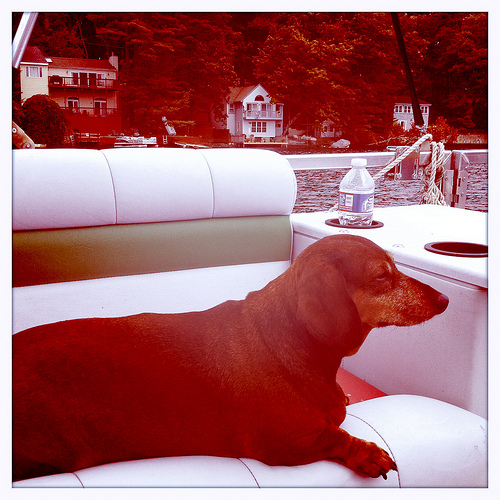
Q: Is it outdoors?
A: Yes, it is outdoors.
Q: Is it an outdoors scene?
A: Yes, it is outdoors.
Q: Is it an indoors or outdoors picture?
A: It is outdoors.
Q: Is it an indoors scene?
A: No, it is outdoors.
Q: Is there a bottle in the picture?
A: Yes, there is a bottle.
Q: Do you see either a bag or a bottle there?
A: Yes, there is a bottle.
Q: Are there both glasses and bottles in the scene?
A: No, there is a bottle but no glasses.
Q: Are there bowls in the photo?
A: No, there are no bowls.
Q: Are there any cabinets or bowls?
A: No, there are no bowls or cabinets.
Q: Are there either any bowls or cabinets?
A: No, there are no bowls or cabinets.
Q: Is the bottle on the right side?
A: Yes, the bottle is on the right of the image.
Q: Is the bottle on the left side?
A: No, the bottle is on the right of the image.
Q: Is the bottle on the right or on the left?
A: The bottle is on the right of the image.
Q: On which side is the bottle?
A: The bottle is on the right of the image.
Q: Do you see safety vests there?
A: No, there are no safety vests.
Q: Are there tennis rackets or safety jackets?
A: No, there are no safety jackets or tennis rackets.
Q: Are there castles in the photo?
A: No, there are no castles.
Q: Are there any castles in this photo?
A: No, there are no castles.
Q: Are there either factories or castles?
A: No, there are no castles or factories.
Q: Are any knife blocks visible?
A: No, there are no knife blocks.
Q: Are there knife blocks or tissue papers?
A: No, there are no knife blocks or tissue papers.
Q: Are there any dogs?
A: Yes, there is a dog.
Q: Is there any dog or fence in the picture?
A: Yes, there is a dog.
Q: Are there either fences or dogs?
A: Yes, there is a dog.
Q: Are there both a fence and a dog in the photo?
A: No, there is a dog but no fences.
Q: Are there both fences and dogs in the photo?
A: No, there is a dog but no fences.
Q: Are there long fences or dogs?
A: Yes, there is a long dog.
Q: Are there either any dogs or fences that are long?
A: Yes, the dog is long.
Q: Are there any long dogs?
A: Yes, there is a long dog.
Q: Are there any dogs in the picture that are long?
A: Yes, there is a dog that is long.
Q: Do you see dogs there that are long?
A: Yes, there is a dog that is long.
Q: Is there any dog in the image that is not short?
A: Yes, there is a long dog.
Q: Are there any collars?
A: No, there are no collars.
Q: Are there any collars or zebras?
A: No, there are no collars or zebras.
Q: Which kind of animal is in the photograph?
A: The animal is a dog.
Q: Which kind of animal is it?
A: The animal is a dog.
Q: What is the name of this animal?
A: This is a dog.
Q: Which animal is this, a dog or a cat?
A: This is a dog.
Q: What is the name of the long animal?
A: The animal is a dog.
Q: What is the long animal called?
A: The animal is a dog.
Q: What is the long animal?
A: The animal is a dog.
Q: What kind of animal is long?
A: The animal is a dog.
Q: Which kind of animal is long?
A: The animal is a dog.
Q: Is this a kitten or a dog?
A: This is a dog.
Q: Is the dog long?
A: Yes, the dog is long.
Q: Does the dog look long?
A: Yes, the dog is long.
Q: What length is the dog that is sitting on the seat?
A: The dog is long.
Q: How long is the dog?
A: The dog is long.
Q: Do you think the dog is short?
A: No, the dog is long.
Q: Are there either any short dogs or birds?
A: No, there is a dog but it is long.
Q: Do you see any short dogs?
A: No, there is a dog but it is long.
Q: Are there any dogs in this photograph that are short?
A: No, there is a dog but it is long.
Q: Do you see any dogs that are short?
A: No, there is a dog but it is long.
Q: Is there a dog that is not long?
A: No, there is a dog but it is long.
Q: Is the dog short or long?
A: The dog is long.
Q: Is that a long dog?
A: Yes, that is a long dog.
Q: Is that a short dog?
A: No, that is a long dog.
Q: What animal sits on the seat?
A: The animal is a dog.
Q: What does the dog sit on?
A: The dog sits on the seat.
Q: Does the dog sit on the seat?
A: Yes, the dog sits on the seat.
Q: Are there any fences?
A: No, there are no fences.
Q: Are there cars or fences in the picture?
A: No, there are no fences or cars.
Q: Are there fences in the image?
A: No, there are no fences.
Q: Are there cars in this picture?
A: No, there are no cars.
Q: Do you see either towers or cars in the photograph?
A: No, there are no cars or towers.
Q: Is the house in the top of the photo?
A: Yes, the house is in the top of the image.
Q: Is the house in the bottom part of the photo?
A: No, the house is in the top of the image.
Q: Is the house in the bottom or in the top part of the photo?
A: The house is in the top of the image.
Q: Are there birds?
A: No, there are no birds.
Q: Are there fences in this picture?
A: No, there are no fences.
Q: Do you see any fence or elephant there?
A: No, there are no fences or elephants.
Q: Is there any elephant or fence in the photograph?
A: No, there are no fences or elephants.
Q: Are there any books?
A: No, there are no books.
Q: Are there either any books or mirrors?
A: No, there are no books or mirrors.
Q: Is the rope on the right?
A: Yes, the rope is on the right of the image.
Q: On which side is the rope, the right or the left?
A: The rope is on the right of the image.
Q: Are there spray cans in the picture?
A: No, there are no spray cans.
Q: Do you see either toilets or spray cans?
A: No, there are no spray cans or toilets.